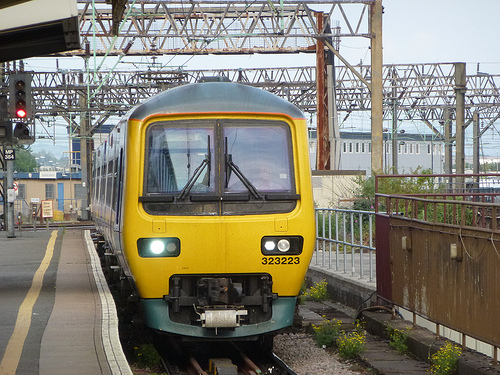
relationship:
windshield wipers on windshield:
[195, 129, 245, 203] [135, 111, 299, 234]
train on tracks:
[82, 80, 313, 343] [181, 354, 299, 374]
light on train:
[122, 223, 193, 261] [82, 80, 313, 343]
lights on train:
[128, 231, 306, 263] [82, 80, 313, 343]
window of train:
[92, 151, 120, 199] [82, 80, 313, 343]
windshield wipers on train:
[195, 129, 245, 203] [82, 80, 313, 343]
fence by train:
[375, 174, 489, 325] [82, 80, 313, 343]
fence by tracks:
[375, 174, 489, 325] [181, 354, 299, 374]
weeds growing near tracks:
[313, 315, 360, 356] [181, 354, 299, 374]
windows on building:
[401, 144, 433, 150] [315, 129, 450, 173]